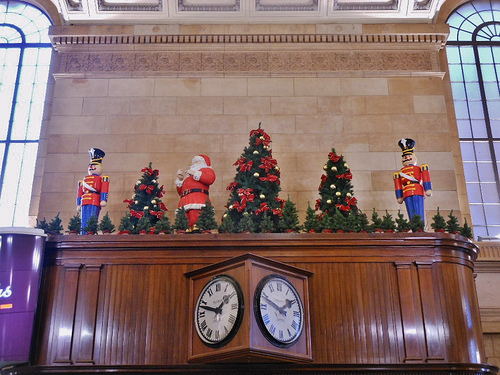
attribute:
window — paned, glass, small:
[420, 41, 490, 181]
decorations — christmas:
[69, 123, 439, 213]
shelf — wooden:
[54, 220, 451, 372]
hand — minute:
[191, 291, 234, 323]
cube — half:
[144, 234, 322, 370]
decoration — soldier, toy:
[358, 131, 456, 239]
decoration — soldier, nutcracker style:
[59, 144, 121, 228]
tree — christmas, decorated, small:
[219, 128, 319, 257]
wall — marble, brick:
[102, 58, 429, 196]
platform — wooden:
[328, 265, 420, 370]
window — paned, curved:
[4, 13, 70, 236]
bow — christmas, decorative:
[211, 180, 251, 217]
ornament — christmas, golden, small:
[314, 161, 361, 207]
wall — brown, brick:
[50, 60, 438, 217]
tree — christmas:
[217, 122, 286, 231]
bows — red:
[250, 199, 270, 216]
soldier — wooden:
[386, 127, 432, 229]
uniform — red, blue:
[387, 165, 436, 224]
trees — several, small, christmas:
[65, 201, 458, 232]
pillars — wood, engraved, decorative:
[46, 259, 107, 363]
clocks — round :
[164, 250, 357, 370]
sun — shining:
[3, 49, 33, 139]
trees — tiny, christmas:
[34, 213, 475, 243]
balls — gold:
[248, 132, 265, 184]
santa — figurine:
[164, 146, 214, 228]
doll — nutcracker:
[391, 135, 438, 236]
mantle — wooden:
[41, 234, 481, 373]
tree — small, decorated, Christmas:
[226, 120, 290, 225]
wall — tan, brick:
[49, 79, 459, 232]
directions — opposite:
[186, 256, 313, 368]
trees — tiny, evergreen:
[33, 211, 479, 250]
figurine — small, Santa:
[172, 146, 230, 235]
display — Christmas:
[44, 130, 480, 242]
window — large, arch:
[443, 0, 499, 243]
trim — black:
[443, 37, 496, 51]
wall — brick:
[27, 24, 469, 239]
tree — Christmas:
[222, 114, 292, 234]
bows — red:
[234, 121, 284, 224]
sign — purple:
[3, 231, 46, 365]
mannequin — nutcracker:
[70, 139, 116, 233]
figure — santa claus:
[173, 151, 221, 234]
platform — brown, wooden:
[40, 226, 491, 370]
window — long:
[0, 2, 56, 227]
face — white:
[199, 283, 238, 340]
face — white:
[259, 282, 300, 338]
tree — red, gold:
[113, 159, 173, 235]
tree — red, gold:
[217, 110, 303, 231]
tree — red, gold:
[287, 145, 377, 236]